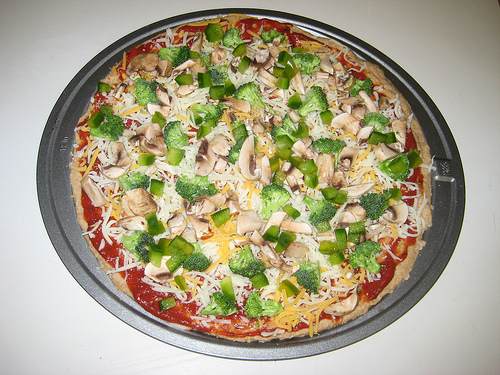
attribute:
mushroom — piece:
[95, 159, 250, 230]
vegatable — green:
[122, 218, 209, 274]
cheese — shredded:
[392, 196, 426, 253]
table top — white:
[1, 1, 498, 373]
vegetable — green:
[161, 117, 192, 154]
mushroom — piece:
[73, 161, 112, 217]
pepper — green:
[162, 144, 187, 166]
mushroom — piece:
[238, 222, 268, 241]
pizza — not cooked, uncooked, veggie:
[67, 15, 439, 335]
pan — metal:
[40, 5, 468, 366]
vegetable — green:
[202, 21, 224, 44]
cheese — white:
[402, 179, 427, 223]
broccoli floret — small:
[226, 243, 267, 274]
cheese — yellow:
[78, 146, 98, 181]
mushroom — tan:
[236, 134, 271, 179]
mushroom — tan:
[261, 210, 309, 234]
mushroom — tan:
[123, 185, 158, 216]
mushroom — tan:
[329, 110, 361, 142]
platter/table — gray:
[7, 0, 493, 370]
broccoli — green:
[159, 44, 190, 62]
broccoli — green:
[125, 78, 164, 101]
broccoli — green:
[83, 105, 123, 139]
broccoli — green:
[228, 242, 266, 273]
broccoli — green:
[358, 188, 398, 216]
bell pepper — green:
[273, 122, 298, 169]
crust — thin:
[400, 110, 441, 225]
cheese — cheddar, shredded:
[207, 215, 219, 237]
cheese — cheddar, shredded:
[301, 298, 326, 313]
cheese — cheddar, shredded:
[306, 310, 313, 337]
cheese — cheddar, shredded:
[268, 323, 291, 328]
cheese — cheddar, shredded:
[277, 316, 297, 323]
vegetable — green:
[162, 120, 193, 162]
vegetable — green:
[298, 272, 318, 288]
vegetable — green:
[344, 239, 385, 276]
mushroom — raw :
[228, 147, 275, 184]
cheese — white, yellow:
[70, 13, 437, 342]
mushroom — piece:
[238, 142, 262, 174]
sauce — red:
[68, 27, 454, 330]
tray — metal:
[40, 97, 76, 256]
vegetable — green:
[135, 75, 166, 105]